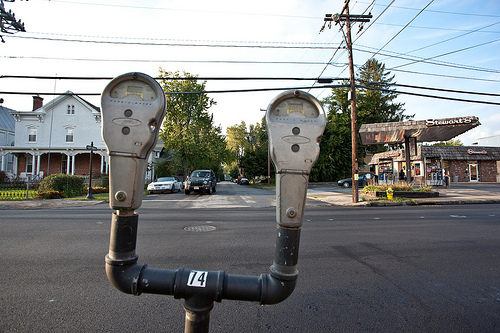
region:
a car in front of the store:
[344, 173, 370, 188]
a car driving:
[186, 172, 215, 193]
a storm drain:
[183, 223, 217, 231]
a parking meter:
[92, 64, 326, 309]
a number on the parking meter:
[182, 265, 211, 292]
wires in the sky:
[11, 10, 484, 97]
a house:
[13, 93, 104, 190]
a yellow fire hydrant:
[385, 188, 395, 199]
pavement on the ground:
[328, 210, 498, 326]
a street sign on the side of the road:
[85, 143, 96, 200]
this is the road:
[370, 210, 457, 317]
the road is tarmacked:
[377, 204, 457, 318]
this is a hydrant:
[65, 77, 337, 316]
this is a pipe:
[103, 250, 297, 305]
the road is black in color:
[339, 238, 426, 328]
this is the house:
[8, 95, 87, 170]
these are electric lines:
[394, 28, 446, 111]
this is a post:
[344, 65, 363, 190]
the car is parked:
[188, 170, 220, 198]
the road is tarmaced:
[358, 254, 468, 315]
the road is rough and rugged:
[375, 253, 497, 329]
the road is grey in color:
[361, 234, 482, 331]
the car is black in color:
[178, 170, 218, 195]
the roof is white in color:
[45, 112, 92, 144]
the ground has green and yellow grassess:
[363, 173, 446, 189]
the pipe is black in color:
[236, 273, 296, 298]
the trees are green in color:
[173, 95, 213, 166]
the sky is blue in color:
[431, 22, 483, 61]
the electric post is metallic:
[346, 130, 363, 194]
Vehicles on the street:
[148, 170, 216, 194]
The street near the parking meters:
[3, 179, 499, 331]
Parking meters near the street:
[100, 73, 327, 331]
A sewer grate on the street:
[186, 223, 214, 233]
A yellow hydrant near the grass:
[385, 185, 395, 198]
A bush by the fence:
[38, 175, 84, 195]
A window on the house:
[65, 100, 75, 114]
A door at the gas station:
[469, 163, 478, 182]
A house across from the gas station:
[11, 92, 162, 187]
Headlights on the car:
[186, 180, 209, 184]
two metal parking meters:
[100, 71, 327, 331]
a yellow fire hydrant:
[382, 182, 397, 198]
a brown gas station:
[359, 116, 499, 186]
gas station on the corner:
[324, 115, 494, 205]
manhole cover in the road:
[181, 222, 219, 235]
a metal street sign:
[85, 140, 97, 199]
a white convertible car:
[145, 173, 181, 193]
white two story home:
[3, 90, 165, 192]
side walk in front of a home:
[1, 192, 102, 208]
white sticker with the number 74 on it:
[186, 270, 208, 287]